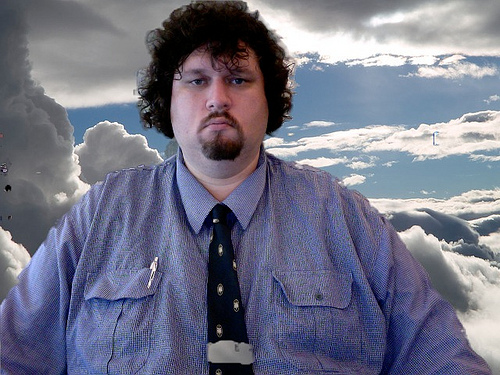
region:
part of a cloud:
[431, 123, 460, 163]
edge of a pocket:
[282, 290, 303, 322]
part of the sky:
[431, 162, 453, 180]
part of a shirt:
[321, 255, 328, 280]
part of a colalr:
[203, 206, 210, 209]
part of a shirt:
[316, 308, 328, 319]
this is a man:
[93, 11, 367, 370]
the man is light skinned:
[233, 93, 256, 102]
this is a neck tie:
[212, 221, 232, 342]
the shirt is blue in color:
[285, 200, 331, 260]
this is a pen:
[143, 254, 161, 286]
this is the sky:
[339, 60, 424, 129]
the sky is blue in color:
[385, 90, 412, 104]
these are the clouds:
[440, 239, 497, 304]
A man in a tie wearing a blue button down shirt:
[17, 8, 427, 364]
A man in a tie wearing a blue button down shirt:
[15, 10, 445, 365]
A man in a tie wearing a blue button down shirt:
[27, 5, 417, 360]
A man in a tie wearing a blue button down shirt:
[15, 5, 432, 365]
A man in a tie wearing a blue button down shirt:
[10, 5, 420, 362]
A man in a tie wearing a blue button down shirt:
[17, 12, 430, 367]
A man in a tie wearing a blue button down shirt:
[14, 9, 425, 370]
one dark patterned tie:
[200, 201, 267, 373]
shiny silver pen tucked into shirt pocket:
[79, 257, 166, 307]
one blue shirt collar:
[172, 153, 274, 233]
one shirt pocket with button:
[266, 264, 361, 374]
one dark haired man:
[133, 4, 293, 171]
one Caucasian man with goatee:
[139, 4, 289, 179]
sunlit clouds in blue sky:
[320, 29, 496, 180]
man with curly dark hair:
[131, 4, 299, 165]